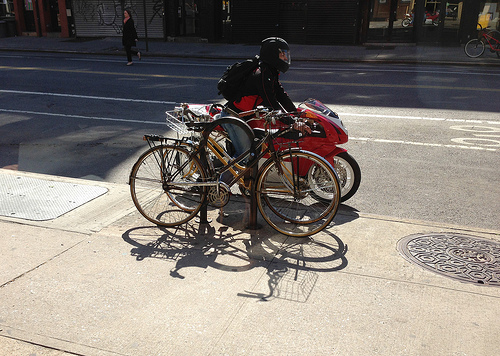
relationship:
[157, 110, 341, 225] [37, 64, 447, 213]
yellow bike on road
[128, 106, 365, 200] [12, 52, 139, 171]
cycle on road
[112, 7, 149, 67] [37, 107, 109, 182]
woman on road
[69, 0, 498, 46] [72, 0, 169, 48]
shop has shutter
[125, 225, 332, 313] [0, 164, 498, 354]
shadow on sidewalk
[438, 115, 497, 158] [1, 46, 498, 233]
letters on street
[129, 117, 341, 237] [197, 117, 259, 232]
bicycle on u pole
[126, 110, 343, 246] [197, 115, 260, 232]
yellow bike on u pole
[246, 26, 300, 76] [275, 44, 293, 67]
helmet has visor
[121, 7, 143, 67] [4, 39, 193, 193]
woman cross street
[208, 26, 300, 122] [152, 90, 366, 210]
person rides motorcycle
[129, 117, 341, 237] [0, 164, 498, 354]
bicycle on sidewalk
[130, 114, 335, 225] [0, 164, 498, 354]
bicycle on sidewalk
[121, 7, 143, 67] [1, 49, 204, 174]
woman on street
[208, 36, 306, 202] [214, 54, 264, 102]
person wears backpack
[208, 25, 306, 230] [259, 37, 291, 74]
person wears helmet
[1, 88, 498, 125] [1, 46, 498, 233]
lines on street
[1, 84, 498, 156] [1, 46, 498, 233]
lines on street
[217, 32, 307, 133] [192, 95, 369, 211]
person on motorcycle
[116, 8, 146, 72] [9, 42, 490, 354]
pedestrian in road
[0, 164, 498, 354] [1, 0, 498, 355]
sidewalk in city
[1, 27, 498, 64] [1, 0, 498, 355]
sidewalk in city